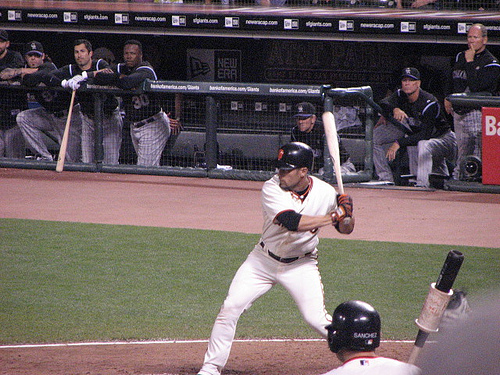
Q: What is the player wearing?
A: A white uniform.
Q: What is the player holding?
A: A bath.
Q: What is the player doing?
A: About to swing.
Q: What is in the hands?
A: A bat.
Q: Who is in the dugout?
A: Players.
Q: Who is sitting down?
A: A older man.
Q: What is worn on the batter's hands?
A: Gloves.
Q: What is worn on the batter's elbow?
A: A brace.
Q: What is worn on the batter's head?
A: A helmet.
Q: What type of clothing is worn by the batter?
A: A uniform.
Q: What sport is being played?
A: Baseball.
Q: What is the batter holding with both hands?
A: A bat.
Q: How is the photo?
A: Clear.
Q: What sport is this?
A: Baseball.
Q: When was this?
A: Daytime.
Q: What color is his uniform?
A: White.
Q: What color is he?
A: White.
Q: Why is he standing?
A: To hit the ball.